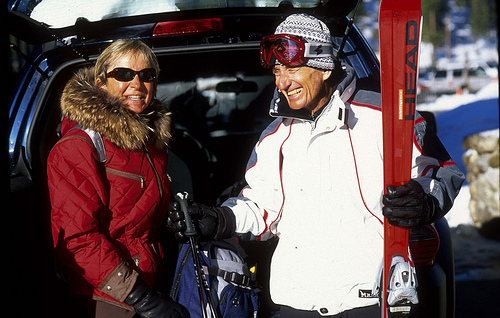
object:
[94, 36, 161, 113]
head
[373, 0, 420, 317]
skis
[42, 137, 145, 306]
arm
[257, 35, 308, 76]
goggles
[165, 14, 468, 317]
man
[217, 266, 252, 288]
buckle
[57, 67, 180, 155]
brown fur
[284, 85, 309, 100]
smile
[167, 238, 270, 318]
blue backpack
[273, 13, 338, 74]
knit hat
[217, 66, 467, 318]
man coat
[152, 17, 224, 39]
break light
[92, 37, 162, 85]
hair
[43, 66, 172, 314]
winter jacket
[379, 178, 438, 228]
hand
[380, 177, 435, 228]
glove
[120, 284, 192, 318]
glove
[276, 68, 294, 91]
nose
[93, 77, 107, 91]
ear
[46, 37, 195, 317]
person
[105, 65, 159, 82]
sunglasses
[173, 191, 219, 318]
ski pole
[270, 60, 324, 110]
face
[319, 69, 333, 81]
ear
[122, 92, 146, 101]
smile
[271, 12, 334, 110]
head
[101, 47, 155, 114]
face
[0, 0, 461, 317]
car